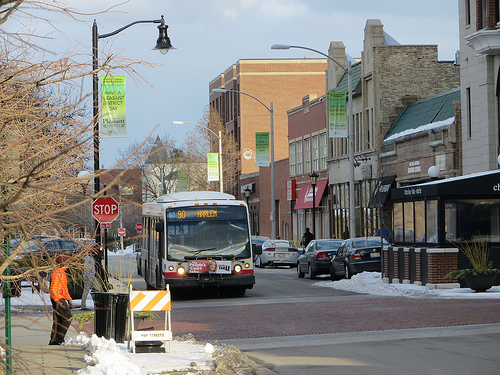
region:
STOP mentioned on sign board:
[93, 199, 119, 225]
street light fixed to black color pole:
[90, 21, 103, 201]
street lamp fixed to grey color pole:
[270, 99, 275, 234]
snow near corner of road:
[349, 281, 414, 297]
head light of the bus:
[174, 265, 184, 277]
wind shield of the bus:
[166, 209, 248, 257]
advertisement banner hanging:
[326, 89, 349, 140]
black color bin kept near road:
[89, 289, 126, 344]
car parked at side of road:
[298, 237, 380, 276]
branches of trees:
[0, 69, 63, 252]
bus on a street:
[128, 185, 260, 303]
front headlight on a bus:
[228, 262, 243, 276]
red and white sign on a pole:
[88, 192, 121, 230]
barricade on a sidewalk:
[121, 279, 178, 359]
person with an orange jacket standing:
[41, 252, 78, 351]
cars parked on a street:
[291, 234, 391, 284]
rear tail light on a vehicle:
[349, 247, 363, 266]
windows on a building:
[386, 195, 441, 248]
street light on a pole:
[112, 9, 183, 58]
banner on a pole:
[326, 87, 351, 141]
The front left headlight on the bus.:
[175, 266, 185, 276]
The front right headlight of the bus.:
[231, 263, 240, 273]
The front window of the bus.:
[166, 225, 248, 259]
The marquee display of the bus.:
[177, 209, 222, 220]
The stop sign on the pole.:
[92, 194, 120, 224]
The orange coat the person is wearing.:
[47, 267, 72, 305]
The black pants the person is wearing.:
[47, 301, 69, 344]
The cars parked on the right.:
[251, 225, 390, 284]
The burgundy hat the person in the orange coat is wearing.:
[57, 255, 69, 262]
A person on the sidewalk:
[46, 254, 74, 344]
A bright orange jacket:
[49, 266, 72, 301]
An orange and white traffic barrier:
[126, 281, 175, 354]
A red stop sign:
[90, 194, 122, 225]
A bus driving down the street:
[139, 190, 256, 295]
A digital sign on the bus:
[171, 207, 244, 219]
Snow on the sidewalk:
[61, 332, 253, 374]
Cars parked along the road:
[246, 234, 395, 284]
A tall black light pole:
[89, 14, 178, 276]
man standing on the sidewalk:
[48, 255, 73, 344]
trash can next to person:
[90, 291, 133, 345]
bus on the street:
[138, 188, 259, 300]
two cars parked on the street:
[294, 238, 384, 277]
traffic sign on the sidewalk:
[90, 197, 118, 278]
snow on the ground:
[70, 330, 213, 374]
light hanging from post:
[92, 15, 180, 289]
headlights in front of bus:
[171, 266, 250, 275]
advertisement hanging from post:
[95, 70, 130, 140]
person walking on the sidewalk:
[302, 225, 314, 252]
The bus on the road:
[139, 192, 255, 294]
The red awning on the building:
[293, 176, 330, 209]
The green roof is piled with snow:
[380, 82, 465, 142]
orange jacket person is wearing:
[47, 264, 72, 304]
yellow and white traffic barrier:
[128, 284, 171, 355]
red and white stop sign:
[88, 195, 120, 223]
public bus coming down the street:
[140, 187, 255, 297]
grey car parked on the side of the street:
[255, 237, 300, 267]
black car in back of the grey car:
[295, 238, 348, 279]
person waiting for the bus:
[50, 253, 73, 346]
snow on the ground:
[311, 269, 498, 302]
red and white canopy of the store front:
[292, 179, 327, 210]